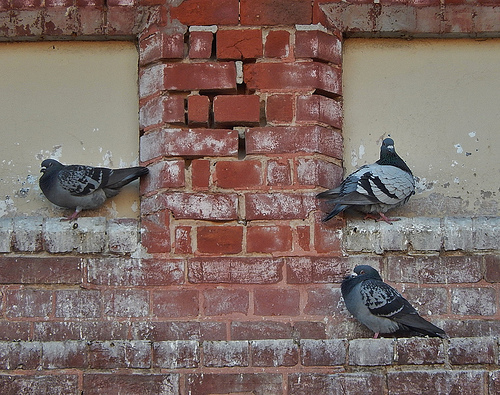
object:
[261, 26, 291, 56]
brick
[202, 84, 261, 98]
hole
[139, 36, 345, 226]
brick chimney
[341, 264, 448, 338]
duck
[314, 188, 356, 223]
tail feathers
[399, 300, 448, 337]
tail feathers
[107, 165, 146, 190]
tail feathers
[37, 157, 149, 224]
bird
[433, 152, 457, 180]
ground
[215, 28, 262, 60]
brick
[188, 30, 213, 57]
brick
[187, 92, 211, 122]
brick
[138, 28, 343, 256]
wall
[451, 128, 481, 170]
chips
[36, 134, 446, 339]
three pigeons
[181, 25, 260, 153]
loose bricks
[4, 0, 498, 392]
building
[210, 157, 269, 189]
brick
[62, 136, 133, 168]
paint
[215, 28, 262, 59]
tile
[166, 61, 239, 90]
tile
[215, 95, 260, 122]
tile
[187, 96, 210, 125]
tile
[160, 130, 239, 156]
tile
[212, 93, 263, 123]
brick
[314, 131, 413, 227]
dove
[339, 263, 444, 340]
dove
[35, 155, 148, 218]
dove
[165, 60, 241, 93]
brick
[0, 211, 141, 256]
ledge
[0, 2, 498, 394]
fireplace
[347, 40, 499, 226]
wall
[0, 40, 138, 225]
wall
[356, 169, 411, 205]
feathers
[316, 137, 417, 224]
bird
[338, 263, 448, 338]
bird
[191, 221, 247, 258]
bricks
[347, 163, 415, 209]
wing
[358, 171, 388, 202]
tips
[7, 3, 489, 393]
home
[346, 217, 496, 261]
ledge